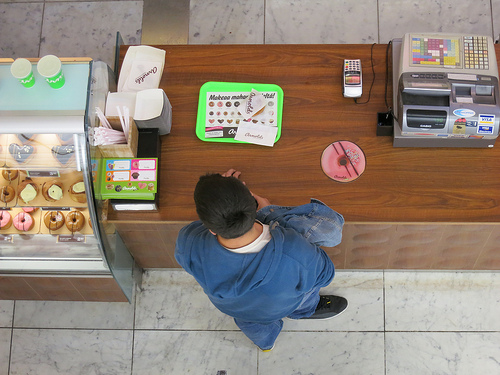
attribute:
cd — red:
[319, 141, 364, 183]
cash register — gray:
[376, 28, 499, 158]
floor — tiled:
[371, 275, 439, 349]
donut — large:
[318, 138, 365, 182]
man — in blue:
[199, 190, 387, 347]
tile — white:
[386, 273, 498, 333]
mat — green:
[183, 71, 296, 147]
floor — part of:
[376, 308, 441, 353]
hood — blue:
[191, 245, 311, 304]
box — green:
[99, 156, 158, 201]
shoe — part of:
[298, 280, 353, 327]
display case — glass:
[10, 60, 127, 299]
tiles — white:
[360, 276, 499, 371]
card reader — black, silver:
[337, 53, 372, 103]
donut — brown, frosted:
[65, 208, 84, 230]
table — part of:
[117, 40, 497, 272]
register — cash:
[385, 24, 498, 151]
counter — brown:
[106, 33, 496, 231]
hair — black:
[191, 172, 256, 238]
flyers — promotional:
[97, 158, 159, 200]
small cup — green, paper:
[2, 49, 38, 98]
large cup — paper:
[34, 46, 75, 91]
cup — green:
[34, 52, 65, 92]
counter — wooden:
[114, 43, 484, 267]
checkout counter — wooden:
[101, 38, 484, 269]